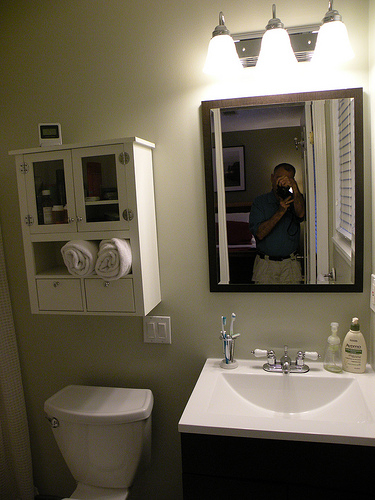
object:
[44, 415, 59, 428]
handle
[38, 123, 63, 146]
clock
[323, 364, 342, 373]
soap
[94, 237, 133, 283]
towel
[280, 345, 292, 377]
faucet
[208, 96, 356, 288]
mirror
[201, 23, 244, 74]
lamps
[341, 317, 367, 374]
lotions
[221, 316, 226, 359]
tooth brushes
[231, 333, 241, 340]
razor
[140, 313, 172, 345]
light switch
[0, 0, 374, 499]
wall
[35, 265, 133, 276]
shelf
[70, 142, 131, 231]
cabinet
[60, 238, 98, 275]
towel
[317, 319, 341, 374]
bottle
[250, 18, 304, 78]
light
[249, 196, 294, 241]
arm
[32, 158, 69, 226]
glass window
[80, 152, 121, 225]
glass window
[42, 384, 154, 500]
toilet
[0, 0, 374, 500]
bathroom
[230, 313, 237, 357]
toothbrushes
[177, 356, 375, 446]
sink